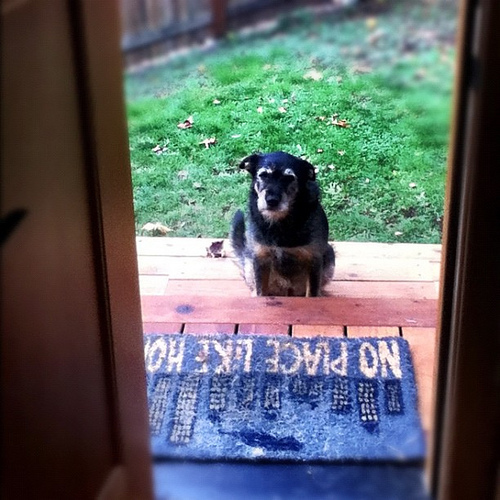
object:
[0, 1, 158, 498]
door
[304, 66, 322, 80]
leaves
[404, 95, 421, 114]
grass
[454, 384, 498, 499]
wall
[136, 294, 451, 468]
door step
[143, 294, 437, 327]
wooden plank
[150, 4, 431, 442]
outside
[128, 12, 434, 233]
yard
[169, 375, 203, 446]
buildings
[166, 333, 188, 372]
letters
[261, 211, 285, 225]
beard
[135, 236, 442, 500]
floor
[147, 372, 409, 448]
drawings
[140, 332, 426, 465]
doormat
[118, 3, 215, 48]
fence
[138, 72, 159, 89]
grass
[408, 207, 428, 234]
grass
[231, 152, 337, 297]
dog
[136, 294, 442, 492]
deck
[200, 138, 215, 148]
leaf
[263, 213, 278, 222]
chin